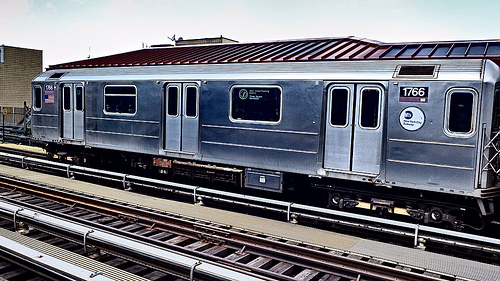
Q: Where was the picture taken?
A: It was taken at the station.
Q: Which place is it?
A: It is a station.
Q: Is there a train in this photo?
A: Yes, there is a train.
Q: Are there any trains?
A: Yes, there is a train.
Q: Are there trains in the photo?
A: Yes, there is a train.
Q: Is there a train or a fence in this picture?
A: Yes, there is a train.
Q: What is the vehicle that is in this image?
A: The vehicle is a train.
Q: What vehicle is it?
A: The vehicle is a train.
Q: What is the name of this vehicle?
A: This is a train.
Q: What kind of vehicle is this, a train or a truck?
A: This is a train.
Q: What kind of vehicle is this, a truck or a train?
A: This is a train.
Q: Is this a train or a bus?
A: This is a train.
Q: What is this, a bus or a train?
A: This is a train.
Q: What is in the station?
A: The train is in the station.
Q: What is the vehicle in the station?
A: The vehicle is a train.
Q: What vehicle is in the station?
A: The vehicle is a train.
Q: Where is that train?
A: The train is in the station.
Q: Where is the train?
A: The train is in the station.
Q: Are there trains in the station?
A: Yes, there is a train in the station.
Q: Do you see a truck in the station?
A: No, there is a train in the station.